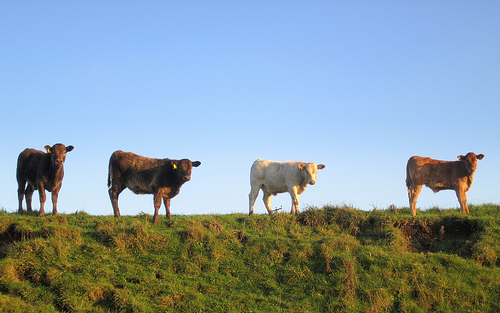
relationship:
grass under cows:
[58, 228, 355, 298] [244, 154, 327, 217]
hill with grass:
[12, 210, 474, 304] [2, 205, 497, 309]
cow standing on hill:
[406, 147, 488, 212] [3, 211, 498, 311]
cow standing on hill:
[244, 158, 328, 211] [3, 211, 498, 311]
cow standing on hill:
[7, 138, 77, 213] [3, 211, 498, 311]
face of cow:
[299, 162, 328, 191] [224, 132, 337, 224]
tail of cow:
[106, 160, 118, 188] [105, 147, 202, 221]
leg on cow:
[38, 181, 45, 216] [15, 143, 75, 215]